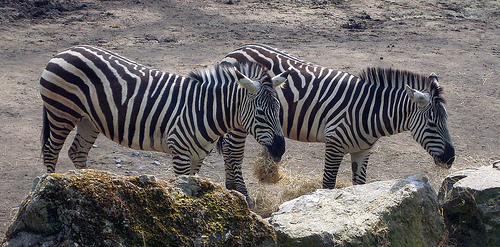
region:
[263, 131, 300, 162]
Zebra has black nose.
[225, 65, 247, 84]
Tip of zebra's ear is black.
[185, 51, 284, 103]
Zebra has black and white mane.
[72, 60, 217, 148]
Zebra is black and white.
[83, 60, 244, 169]
Zebra is covered in stripes.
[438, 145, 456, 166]
Zebra has black nose.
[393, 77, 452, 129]
Zebra has white ear.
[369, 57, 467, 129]
Zebra has black and white mane.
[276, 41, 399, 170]
Zebra is black and white.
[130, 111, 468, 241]
Zebra's standing behind large rocks.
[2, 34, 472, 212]
there are 2 zebras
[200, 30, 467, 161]
the zebras are black and white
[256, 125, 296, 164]
the nose is black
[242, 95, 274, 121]
the eye is open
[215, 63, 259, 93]
the tip of the ear is black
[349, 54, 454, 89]
the mane is black and white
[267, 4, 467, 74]
the dirt is light brown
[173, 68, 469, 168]
the zebras are facing to the right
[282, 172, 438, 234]
the sun is on the rock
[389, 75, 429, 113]
the ear is white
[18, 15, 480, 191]
Two zebras standing together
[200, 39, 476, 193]
Zebras looking at rocks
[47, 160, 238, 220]
Moss on top of rock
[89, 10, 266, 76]
Tracks in the dust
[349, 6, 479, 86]
Pebbles on the dirt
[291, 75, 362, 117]
Stripes are black and white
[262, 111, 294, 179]
Zebras nose is black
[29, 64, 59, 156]
Long hair on end of tail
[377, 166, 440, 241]
Shadow on the rock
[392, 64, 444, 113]
Zebra has large ears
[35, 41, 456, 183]
Two zebras eating.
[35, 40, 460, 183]
Two zebras grazing.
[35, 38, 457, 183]
Two zebras eating hay.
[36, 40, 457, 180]
Two zebras eating contentedly.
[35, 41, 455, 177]
Two zebras eating grass.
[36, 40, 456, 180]
Two zebras eating food together.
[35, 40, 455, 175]
Two zebras eating grass together.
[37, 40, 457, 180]
Two zebras happily chewing on hay.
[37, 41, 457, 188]
Two black and white zebras eating together.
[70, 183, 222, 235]
Moss growing on side of rock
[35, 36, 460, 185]
Two zebras standing next to large rocks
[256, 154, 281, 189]
Ball of dried up grass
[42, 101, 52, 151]
Black hair on zebras tail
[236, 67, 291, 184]
Zebra eating ball of grass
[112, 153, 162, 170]
Small scattered rocks on ground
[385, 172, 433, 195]
Shadow from zebra on rock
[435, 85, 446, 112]
Black hair on zebras forehead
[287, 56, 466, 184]
Zebra looking at rock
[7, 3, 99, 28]
Black area on ground